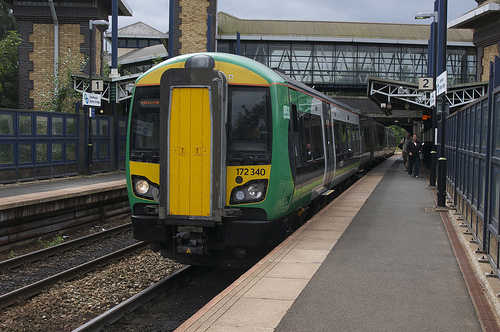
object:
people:
[405, 134, 423, 179]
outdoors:
[5, 2, 485, 326]